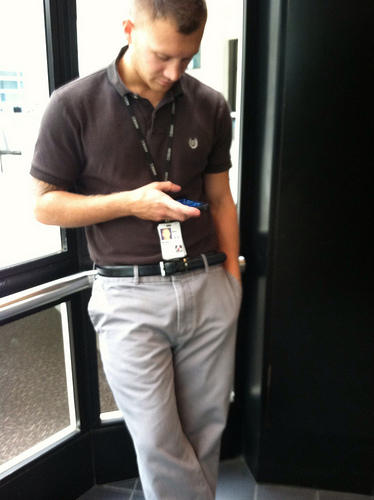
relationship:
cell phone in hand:
[175, 196, 208, 213] [134, 184, 198, 221]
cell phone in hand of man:
[175, 196, 208, 213] [32, 0, 241, 498]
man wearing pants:
[32, 0, 241, 498] [92, 248, 286, 483]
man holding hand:
[32, 0, 241, 498] [214, 261, 248, 336]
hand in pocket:
[214, 261, 248, 336] [221, 276, 245, 333]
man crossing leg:
[32, 0, 241, 498] [84, 275, 211, 498]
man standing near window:
[32, 0, 241, 498] [2, 2, 246, 296]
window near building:
[0, 1, 267, 489] [3, 276, 83, 479]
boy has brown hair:
[35, 18, 244, 498] [130, 0, 207, 34]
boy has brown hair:
[27, 0, 244, 497] [130, 0, 207, 34]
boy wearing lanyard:
[35, 18, 244, 498] [154, 219, 185, 263]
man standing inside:
[32, 0, 241, 498] [4, 1, 367, 495]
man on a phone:
[32, 0, 241, 498] [152, 183, 211, 226]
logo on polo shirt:
[186, 136, 199, 147] [27, 42, 233, 268]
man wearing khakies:
[32, 0, 241, 498] [83, 265, 260, 480]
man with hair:
[32, 0, 241, 498] [131, 2, 209, 34]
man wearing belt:
[32, 0, 241, 498] [94, 245, 231, 286]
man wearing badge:
[32, 0, 241, 498] [149, 217, 192, 265]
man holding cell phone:
[32, 0, 241, 498] [175, 196, 208, 213]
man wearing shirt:
[32, 0, 241, 498] [38, 60, 236, 264]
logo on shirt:
[186, 136, 199, 147] [38, 46, 243, 269]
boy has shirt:
[35, 18, 244, 498] [38, 60, 236, 264]